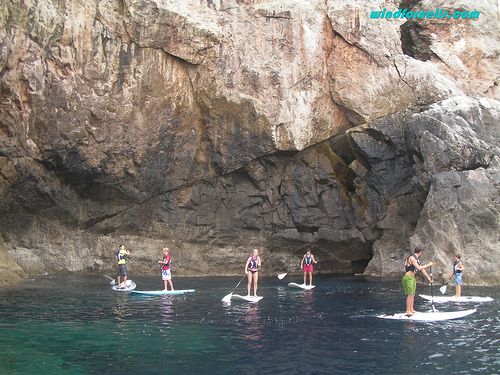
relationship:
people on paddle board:
[107, 232, 462, 317] [231, 293, 265, 303]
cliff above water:
[4, 10, 494, 273] [23, 280, 484, 368]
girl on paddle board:
[234, 228, 261, 309] [231, 293, 265, 303]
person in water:
[244, 248, 263, 293] [23, 280, 484, 368]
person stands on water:
[399, 248, 424, 314] [23, 280, 484, 368]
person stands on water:
[453, 254, 464, 295] [23, 280, 484, 368]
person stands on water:
[113, 246, 130, 285] [23, 280, 484, 368]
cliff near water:
[4, 10, 494, 273] [23, 280, 484, 368]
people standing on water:
[107, 232, 462, 317] [23, 280, 484, 368]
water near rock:
[23, 280, 484, 368] [259, 193, 429, 281]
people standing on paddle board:
[107, 232, 462, 317] [285, 282, 316, 291]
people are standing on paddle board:
[107, 232, 462, 317] [285, 282, 316, 291]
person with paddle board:
[113, 246, 130, 285] [109, 277, 136, 291]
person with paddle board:
[158, 243, 176, 290] [131, 287, 197, 297]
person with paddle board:
[244, 248, 263, 293] [231, 293, 265, 303]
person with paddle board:
[300, 247, 317, 285] [285, 282, 316, 291]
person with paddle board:
[399, 248, 424, 314] [374, 310, 477, 323]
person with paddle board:
[453, 254, 464, 295] [419, 291, 494, 308]